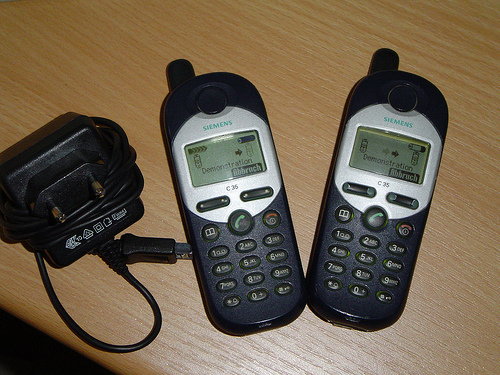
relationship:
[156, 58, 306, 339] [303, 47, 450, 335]
black phone near black phone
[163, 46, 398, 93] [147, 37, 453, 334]
antennas on phones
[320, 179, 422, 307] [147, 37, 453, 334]
buttons on phones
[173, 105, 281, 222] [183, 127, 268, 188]
frame around information window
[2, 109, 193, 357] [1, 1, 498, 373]
charger on table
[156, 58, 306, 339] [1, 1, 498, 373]
black phone on table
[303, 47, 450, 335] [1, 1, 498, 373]
black phone on table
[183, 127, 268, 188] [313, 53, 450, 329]
information window on phone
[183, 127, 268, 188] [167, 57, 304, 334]
information window on phone